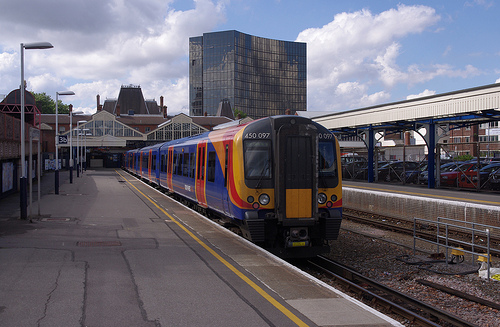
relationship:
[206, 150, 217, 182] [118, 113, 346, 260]
window on train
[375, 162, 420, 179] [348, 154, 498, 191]
car in lot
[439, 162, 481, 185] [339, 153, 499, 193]
car in lot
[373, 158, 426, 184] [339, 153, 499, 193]
car in lot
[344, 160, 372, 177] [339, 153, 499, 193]
car in lot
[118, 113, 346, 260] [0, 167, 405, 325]
train on platform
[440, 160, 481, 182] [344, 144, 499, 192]
car in parking lot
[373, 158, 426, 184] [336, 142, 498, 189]
car in parking lot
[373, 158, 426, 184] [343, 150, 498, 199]
car in parking lot